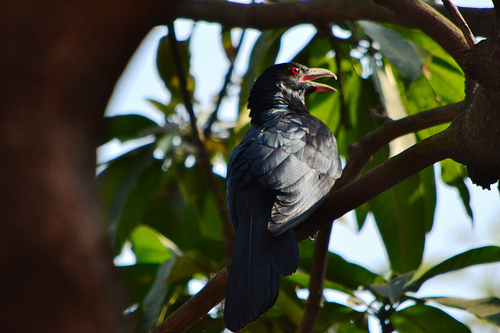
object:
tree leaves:
[426, 290, 499, 323]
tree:
[1, 0, 226, 332]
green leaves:
[387, 306, 469, 332]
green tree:
[343, 1, 499, 332]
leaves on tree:
[371, 182, 425, 282]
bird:
[223, 62, 340, 332]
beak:
[303, 69, 336, 82]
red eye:
[292, 67, 300, 75]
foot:
[309, 229, 320, 242]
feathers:
[224, 219, 299, 333]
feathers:
[249, 62, 308, 112]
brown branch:
[345, 129, 459, 209]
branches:
[160, 1, 437, 31]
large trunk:
[0, 1, 97, 332]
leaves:
[405, 245, 499, 293]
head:
[248, 63, 338, 111]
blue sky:
[97, 18, 242, 138]